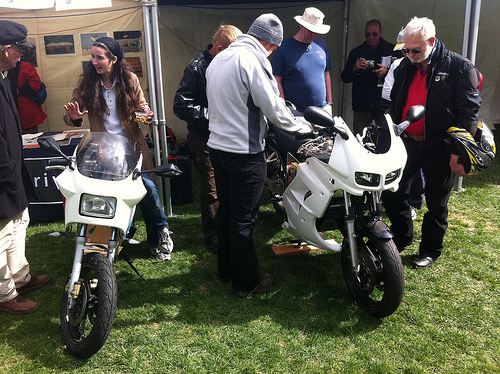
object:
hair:
[402, 16, 436, 42]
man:
[380, 16, 496, 270]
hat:
[293, 6, 331, 35]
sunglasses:
[402, 39, 430, 54]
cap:
[247, 13, 284, 48]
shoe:
[0, 294, 40, 314]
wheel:
[340, 216, 404, 319]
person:
[172, 20, 244, 255]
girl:
[63, 37, 174, 262]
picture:
[43, 33, 76, 56]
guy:
[0, 20, 52, 315]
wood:
[271, 239, 338, 257]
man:
[271, 6, 334, 132]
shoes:
[16, 275, 51, 294]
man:
[204, 13, 312, 298]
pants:
[209, 147, 267, 294]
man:
[381, 28, 425, 220]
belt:
[408, 133, 425, 141]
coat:
[388, 40, 483, 156]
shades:
[392, 28, 405, 51]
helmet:
[444, 118, 497, 176]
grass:
[165, 323, 262, 370]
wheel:
[60, 252, 118, 359]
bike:
[36, 131, 182, 358]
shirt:
[400, 64, 427, 135]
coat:
[63, 65, 158, 185]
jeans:
[139, 172, 170, 248]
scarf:
[86, 72, 131, 104]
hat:
[0, 20, 34, 49]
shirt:
[98, 74, 136, 158]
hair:
[73, 36, 135, 118]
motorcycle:
[262, 99, 427, 318]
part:
[297, 134, 338, 159]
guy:
[340, 19, 405, 138]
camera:
[366, 60, 375, 68]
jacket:
[205, 34, 312, 155]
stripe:
[205, 42, 304, 155]